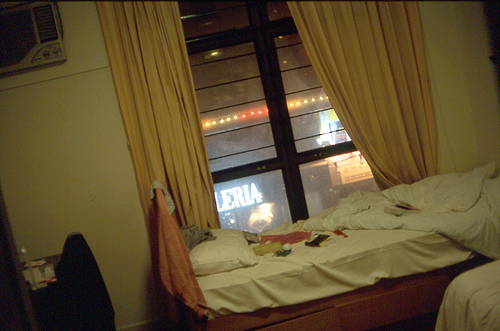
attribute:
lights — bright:
[196, 94, 330, 142]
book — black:
[305, 231, 332, 251]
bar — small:
[191, 52, 262, 69]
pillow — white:
[186, 227, 258, 275]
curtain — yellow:
[282, 0, 444, 183]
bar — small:
[276, 40, 303, 50]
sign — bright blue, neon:
[212, 164, 292, 232]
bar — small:
[191, 75, 263, 93]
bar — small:
[199, 98, 259, 114]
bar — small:
[202, 62, 292, 144]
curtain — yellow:
[93, 0, 221, 258]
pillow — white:
[205, 227, 286, 288]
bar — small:
[201, 120, 271, 135]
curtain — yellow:
[93, 1, 219, 229]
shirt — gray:
[183, 223, 208, 244]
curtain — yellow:
[283, 8, 433, 198]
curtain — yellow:
[85, 4, 236, 263]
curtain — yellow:
[291, 1, 436, 217]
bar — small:
[179, 35, 305, 63]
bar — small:
[183, 70, 323, 87]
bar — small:
[199, 94, 329, 114]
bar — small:
[200, 117, 334, 143]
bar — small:
[290, 82, 328, 102]